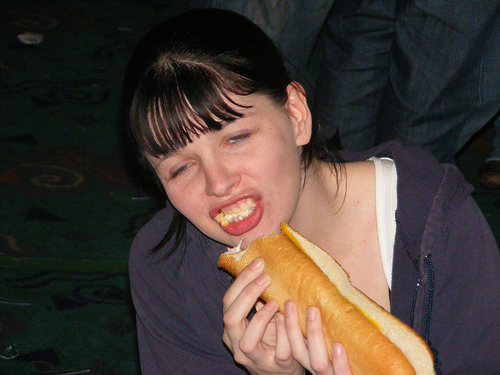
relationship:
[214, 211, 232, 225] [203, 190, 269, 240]
bun in mouth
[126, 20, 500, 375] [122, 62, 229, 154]
girl has bangs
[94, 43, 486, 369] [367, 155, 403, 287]
girl wears shirt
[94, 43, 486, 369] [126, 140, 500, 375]
girl wears sweater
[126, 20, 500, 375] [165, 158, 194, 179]
girl close eye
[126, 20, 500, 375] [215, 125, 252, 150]
girl close eye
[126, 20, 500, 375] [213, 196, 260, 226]
girl showing teeth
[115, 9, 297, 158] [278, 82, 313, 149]
dark hair behind ear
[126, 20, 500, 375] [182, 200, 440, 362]
girl eats hot dog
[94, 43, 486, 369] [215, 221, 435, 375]
girl eats bun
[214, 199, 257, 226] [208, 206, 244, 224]
bun in teeth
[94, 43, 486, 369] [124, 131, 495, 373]
girl wears sweater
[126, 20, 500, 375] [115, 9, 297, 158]
girl has dark hair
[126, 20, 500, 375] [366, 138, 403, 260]
girl wears shirt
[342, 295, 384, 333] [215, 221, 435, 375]
mustard on bun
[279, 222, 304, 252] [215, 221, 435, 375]
mustard on bun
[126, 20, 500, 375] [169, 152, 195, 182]
girl squinting eye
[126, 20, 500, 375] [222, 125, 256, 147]
girl squinting eye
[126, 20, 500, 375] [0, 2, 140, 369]
girl sitting on carpet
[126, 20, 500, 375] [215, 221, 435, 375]
girl eating bun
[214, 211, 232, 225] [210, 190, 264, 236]
bun in mouth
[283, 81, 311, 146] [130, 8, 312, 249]
ear on head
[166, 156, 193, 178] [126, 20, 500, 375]
eye of girl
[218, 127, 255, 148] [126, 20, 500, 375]
eye of girl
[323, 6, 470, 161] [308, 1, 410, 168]
pair of leg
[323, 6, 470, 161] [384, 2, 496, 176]
pair of leg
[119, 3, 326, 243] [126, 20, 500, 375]
head of girl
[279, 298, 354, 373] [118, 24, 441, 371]
hand of woman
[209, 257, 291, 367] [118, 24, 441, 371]
hand of woman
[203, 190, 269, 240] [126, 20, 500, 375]
mouth of girl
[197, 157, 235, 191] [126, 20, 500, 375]
nose of girl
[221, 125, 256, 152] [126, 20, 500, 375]
eye of girl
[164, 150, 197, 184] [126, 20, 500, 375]
eye of girl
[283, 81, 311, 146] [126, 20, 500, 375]
ear of girl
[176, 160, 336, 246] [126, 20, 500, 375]
neck of girl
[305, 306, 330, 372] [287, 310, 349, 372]
finger on hand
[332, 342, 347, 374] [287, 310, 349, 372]
finger on hand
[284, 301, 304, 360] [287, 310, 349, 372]
finger on hand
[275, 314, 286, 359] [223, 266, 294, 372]
finger on hand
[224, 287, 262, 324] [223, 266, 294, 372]
finger on hand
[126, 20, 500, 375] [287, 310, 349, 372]
girl has hand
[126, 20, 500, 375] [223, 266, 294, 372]
girl has hand